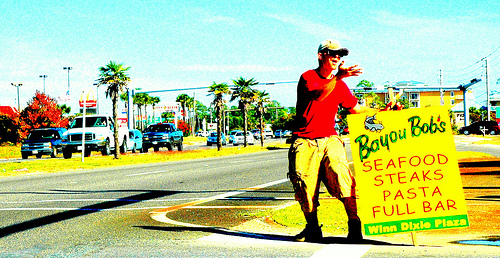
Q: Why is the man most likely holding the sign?
A: Promoting th restaurant.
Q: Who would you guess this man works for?
A: Bayou Bob's.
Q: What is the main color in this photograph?
A: Yellow.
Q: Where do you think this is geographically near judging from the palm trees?
A: The beach.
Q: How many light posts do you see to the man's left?
A: Three.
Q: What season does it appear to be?
A: Summer.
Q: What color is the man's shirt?
A: Red.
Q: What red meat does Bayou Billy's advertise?
A: Steak.